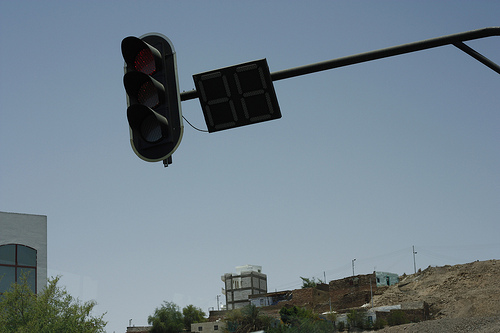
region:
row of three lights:
[109, 30, 183, 157]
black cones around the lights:
[119, 24, 187, 169]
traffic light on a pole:
[106, 25, 206, 174]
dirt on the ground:
[358, 254, 498, 331]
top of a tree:
[2, 268, 118, 331]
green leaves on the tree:
[1, 269, 118, 331]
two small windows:
[195, 319, 225, 331]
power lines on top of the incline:
[313, 236, 439, 291]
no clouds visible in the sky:
[1, 0, 497, 326]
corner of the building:
[38, 210, 58, 290]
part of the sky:
[394, 150, 410, 161]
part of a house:
[231, 277, 278, 332]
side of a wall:
[3, 202, 18, 227]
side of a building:
[235, 281, 250, 296]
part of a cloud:
[327, 205, 369, 261]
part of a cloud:
[323, 139, 388, 215]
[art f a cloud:
[348, 228, 378, 275]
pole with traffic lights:
[107, 18, 492, 168]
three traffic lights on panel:
[122, 28, 187, 125]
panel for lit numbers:
[189, 50, 282, 138]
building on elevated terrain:
[217, 255, 280, 310]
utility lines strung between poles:
[334, 240, 419, 262]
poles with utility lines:
[406, 243, 421, 275]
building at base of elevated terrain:
[188, 315, 228, 331]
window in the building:
[211, 319, 226, 331]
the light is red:
[116, 36, 172, 68]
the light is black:
[125, 25, 187, 167]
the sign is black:
[191, 71, 311, 137]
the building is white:
[218, 249, 274, 319]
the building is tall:
[221, 268, 264, 319]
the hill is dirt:
[211, 261, 495, 330]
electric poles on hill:
[347, 249, 437, 288]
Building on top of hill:
[220, 258, 393, 313]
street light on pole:
[113, 21, 187, 162]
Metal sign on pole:
[189, 60, 286, 137]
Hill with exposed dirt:
[380, 255, 498, 329]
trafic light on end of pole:
[117, 31, 499, 148]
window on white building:
[0, 235, 38, 296]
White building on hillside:
[221, 268, 268, 311]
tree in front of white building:
[2, 278, 104, 327]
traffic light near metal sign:
[116, 33, 189, 168]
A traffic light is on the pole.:
[111, 28, 185, 165]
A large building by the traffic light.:
[210, 261, 272, 308]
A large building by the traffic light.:
[1, 203, 51, 329]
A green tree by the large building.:
[4, 273, 100, 331]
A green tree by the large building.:
[2, 271, 104, 328]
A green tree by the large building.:
[2, 268, 85, 328]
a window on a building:
[1, 240, 18, 262]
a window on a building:
[18, 245, 33, 269]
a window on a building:
[1, 265, 13, 301]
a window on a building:
[18, 264, 30, 296]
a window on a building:
[231, 278, 253, 288]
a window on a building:
[229, 289, 251, 299]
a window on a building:
[215, 326, 219, 331]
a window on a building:
[254, 298, 266, 306]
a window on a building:
[376, 276, 382, 281]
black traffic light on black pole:
[119, 31, 185, 160]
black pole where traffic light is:
[181, 20, 495, 102]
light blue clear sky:
[0, 2, 495, 330]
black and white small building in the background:
[224, 268, 266, 310]